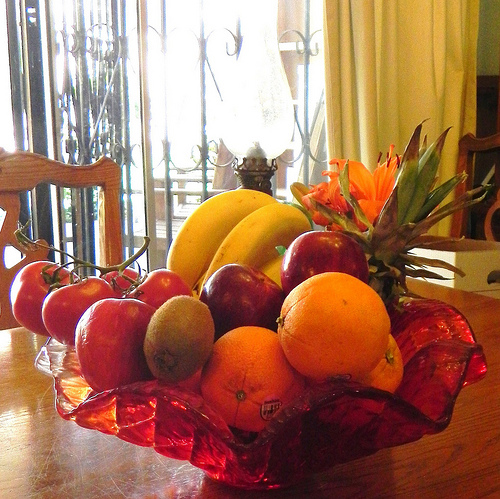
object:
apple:
[76, 296, 164, 395]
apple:
[199, 257, 282, 327]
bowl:
[15, 285, 472, 496]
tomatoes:
[6, 238, 190, 391]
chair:
[0, 142, 128, 332]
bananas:
[164, 187, 311, 297]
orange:
[267, 270, 398, 413]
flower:
[329, 151, 398, 199]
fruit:
[171, 185, 283, 275]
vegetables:
[6, 258, 188, 405]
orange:
[211, 332, 292, 422]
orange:
[367, 331, 410, 396]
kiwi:
[140, 292, 213, 382]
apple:
[284, 233, 371, 288]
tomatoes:
[10, 258, 85, 333]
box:
[394, 234, 497, 296]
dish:
[21, 291, 492, 485]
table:
[3, 269, 498, 496]